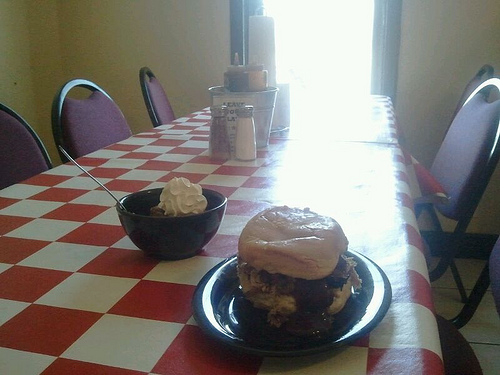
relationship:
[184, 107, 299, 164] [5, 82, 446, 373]
shakers on table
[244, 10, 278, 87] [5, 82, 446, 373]
paper towels on table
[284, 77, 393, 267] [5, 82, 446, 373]
sunlight on table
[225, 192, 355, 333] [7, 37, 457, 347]
food on table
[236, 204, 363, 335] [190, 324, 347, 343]
food on plate